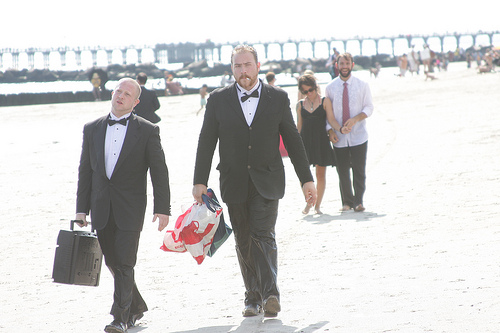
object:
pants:
[93, 200, 150, 324]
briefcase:
[54, 219, 101, 285]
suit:
[75, 112, 172, 317]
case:
[49, 218, 102, 285]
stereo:
[47, 217, 106, 287]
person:
[409, 37, 437, 80]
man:
[92, 78, 162, 331]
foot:
[110, 315, 121, 330]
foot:
[295, 187, 327, 214]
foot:
[335, 190, 347, 199]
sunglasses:
[297, 82, 319, 95]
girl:
[292, 71, 350, 218]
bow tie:
[241, 88, 263, 105]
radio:
[14, 209, 129, 287]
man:
[327, 52, 378, 221]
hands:
[322, 116, 342, 146]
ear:
[133, 99, 156, 103]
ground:
[361, 166, 384, 186]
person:
[296, 70, 341, 215]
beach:
[0, 57, 497, 329]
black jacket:
[75, 114, 171, 216]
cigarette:
[233, 65, 257, 92]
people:
[399, 52, 499, 86]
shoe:
[246, 283, 302, 313]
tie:
[339, 78, 352, 127]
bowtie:
[238, 90, 260, 101]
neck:
[234, 77, 261, 94]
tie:
[233, 84, 263, 104]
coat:
[188, 75, 309, 293]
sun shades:
[297, 84, 318, 96]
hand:
[69, 206, 96, 236]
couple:
[288, 46, 378, 233]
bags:
[149, 173, 239, 271]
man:
[218, 49, 288, 318]